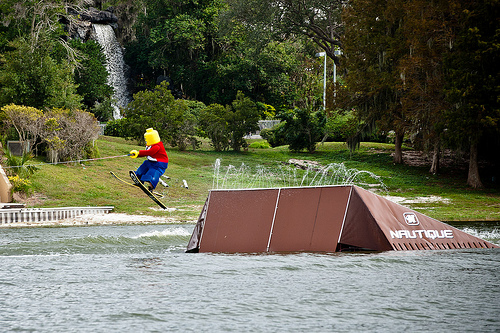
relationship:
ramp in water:
[187, 185, 498, 253] [2, 225, 499, 332]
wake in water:
[0, 231, 189, 262] [2, 225, 499, 332]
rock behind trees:
[75, 9, 119, 39] [0, 4, 499, 185]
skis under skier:
[129, 171, 167, 209] [129, 125, 169, 193]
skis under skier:
[111, 172, 166, 200] [129, 125, 169, 193]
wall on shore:
[0, 206, 116, 229] [0, 140, 499, 217]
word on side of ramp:
[388, 228, 455, 239] [187, 185, 498, 253]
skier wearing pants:
[129, 125, 169, 193] [135, 162, 168, 189]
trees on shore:
[0, 4, 499, 185] [0, 140, 499, 217]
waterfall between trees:
[95, 24, 132, 121] [0, 4, 499, 185]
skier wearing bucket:
[129, 125, 169, 193] [142, 126, 162, 146]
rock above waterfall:
[75, 9, 119, 39] [95, 24, 132, 121]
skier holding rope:
[129, 125, 169, 193] [0, 152, 129, 176]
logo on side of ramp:
[402, 210, 419, 226] [187, 185, 498, 253]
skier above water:
[129, 125, 169, 193] [2, 225, 499, 332]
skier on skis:
[129, 125, 169, 193] [129, 171, 167, 209]